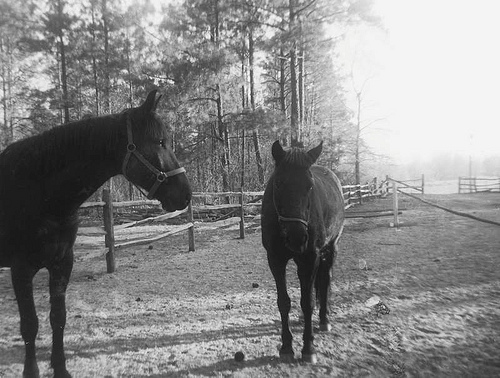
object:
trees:
[0, 0, 392, 198]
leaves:
[170, 10, 191, 31]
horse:
[261, 139, 345, 362]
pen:
[0, 173, 499, 378]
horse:
[1, 89, 191, 377]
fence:
[76, 174, 425, 272]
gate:
[419, 174, 460, 193]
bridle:
[121, 109, 186, 201]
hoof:
[300, 348, 318, 363]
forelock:
[283, 142, 313, 168]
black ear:
[142, 89, 157, 112]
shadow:
[64, 319, 291, 361]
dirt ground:
[0, 191, 499, 378]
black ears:
[306, 141, 326, 161]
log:
[396, 185, 499, 226]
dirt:
[372, 300, 391, 314]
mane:
[0, 112, 133, 158]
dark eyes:
[158, 137, 165, 147]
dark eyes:
[307, 179, 315, 193]